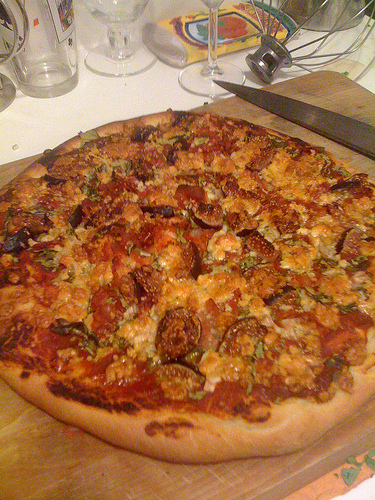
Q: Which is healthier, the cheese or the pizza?
A: The cheese is healthier than the pizza.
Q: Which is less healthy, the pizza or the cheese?
A: The pizza is less healthy than the cheese.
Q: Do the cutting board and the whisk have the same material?
A: No, the cutting board is made of wood and the whisk is made of metal.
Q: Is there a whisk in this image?
A: Yes, there is a whisk.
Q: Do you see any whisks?
A: Yes, there is a whisk.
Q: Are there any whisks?
A: Yes, there is a whisk.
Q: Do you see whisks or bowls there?
A: Yes, there is a whisk.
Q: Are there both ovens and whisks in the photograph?
A: No, there is a whisk but no ovens.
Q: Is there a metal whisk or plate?
A: Yes, there is a metal whisk.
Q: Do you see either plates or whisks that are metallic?
A: Yes, the whisk is metallic.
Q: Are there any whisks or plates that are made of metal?
A: Yes, the whisk is made of metal.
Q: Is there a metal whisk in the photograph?
A: Yes, there is a metal whisk.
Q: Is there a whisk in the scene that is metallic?
A: Yes, there is a whisk that is metallic.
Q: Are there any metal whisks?
A: Yes, there is a whisk that is made of metal.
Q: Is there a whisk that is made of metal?
A: Yes, there is a whisk that is made of metal.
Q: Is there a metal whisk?
A: Yes, there is a whisk that is made of metal.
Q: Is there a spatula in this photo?
A: No, there are no spatulas.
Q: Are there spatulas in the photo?
A: No, there are no spatulas.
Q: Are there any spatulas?
A: No, there are no spatulas.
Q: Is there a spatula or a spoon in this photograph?
A: No, there are no spatulas or spoons.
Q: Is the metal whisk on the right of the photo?
A: Yes, the whisk is on the right of the image.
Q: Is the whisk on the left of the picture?
A: No, the whisk is on the right of the image.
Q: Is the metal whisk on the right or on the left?
A: The whisk is on the right of the image.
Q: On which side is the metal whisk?
A: The whisk is on the right of the image.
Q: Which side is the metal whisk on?
A: The whisk is on the right of the image.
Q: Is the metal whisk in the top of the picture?
A: Yes, the whisk is in the top of the image.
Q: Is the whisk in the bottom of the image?
A: No, the whisk is in the top of the image.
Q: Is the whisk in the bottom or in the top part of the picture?
A: The whisk is in the top of the image.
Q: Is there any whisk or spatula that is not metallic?
A: No, there is a whisk but it is metallic.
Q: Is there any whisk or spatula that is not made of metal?
A: No, there is a whisk but it is made of metal.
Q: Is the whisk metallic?
A: Yes, the whisk is metallic.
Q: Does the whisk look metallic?
A: Yes, the whisk is metallic.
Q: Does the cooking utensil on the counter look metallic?
A: Yes, the whisk is metallic.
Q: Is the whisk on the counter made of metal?
A: Yes, the whisk is made of metal.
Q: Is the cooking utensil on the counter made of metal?
A: Yes, the whisk is made of metal.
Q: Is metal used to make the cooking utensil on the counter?
A: Yes, the whisk is made of metal.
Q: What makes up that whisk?
A: The whisk is made of metal.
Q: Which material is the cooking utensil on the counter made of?
A: The whisk is made of metal.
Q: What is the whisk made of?
A: The whisk is made of metal.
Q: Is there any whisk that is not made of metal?
A: No, there is a whisk but it is made of metal.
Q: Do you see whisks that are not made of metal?
A: No, there is a whisk but it is made of metal.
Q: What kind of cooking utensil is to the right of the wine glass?
A: The cooking utensil is a whisk.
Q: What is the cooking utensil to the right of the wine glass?
A: The cooking utensil is a whisk.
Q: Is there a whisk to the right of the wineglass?
A: Yes, there is a whisk to the right of the wineglass.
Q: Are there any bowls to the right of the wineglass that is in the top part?
A: No, there is a whisk to the right of the wine glass.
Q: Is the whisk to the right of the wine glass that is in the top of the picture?
A: Yes, the whisk is to the right of the wineglass.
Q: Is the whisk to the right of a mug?
A: No, the whisk is to the right of the wineglass.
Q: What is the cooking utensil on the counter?
A: The cooking utensil is a whisk.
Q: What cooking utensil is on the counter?
A: The cooking utensil is a whisk.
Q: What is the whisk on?
A: The whisk is on the counter.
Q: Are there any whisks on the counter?
A: Yes, there is a whisk on the counter.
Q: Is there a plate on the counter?
A: No, there is a whisk on the counter.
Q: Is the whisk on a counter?
A: Yes, the whisk is on a counter.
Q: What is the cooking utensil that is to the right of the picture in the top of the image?
A: The cooking utensil is a whisk.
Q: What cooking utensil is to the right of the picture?
A: The cooking utensil is a whisk.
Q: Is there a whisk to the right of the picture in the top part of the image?
A: Yes, there is a whisk to the right of the picture.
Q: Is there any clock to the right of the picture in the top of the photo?
A: No, there is a whisk to the right of the picture.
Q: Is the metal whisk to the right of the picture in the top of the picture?
A: Yes, the whisk is to the right of the picture.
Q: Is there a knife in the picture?
A: Yes, there is a knife.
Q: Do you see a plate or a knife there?
A: Yes, there is a knife.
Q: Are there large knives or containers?
A: Yes, there is a large knife.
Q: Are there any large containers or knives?
A: Yes, there is a large knife.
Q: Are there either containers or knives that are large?
A: Yes, the knife is large.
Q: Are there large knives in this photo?
A: Yes, there is a large knife.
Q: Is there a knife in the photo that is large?
A: Yes, there is a knife that is large.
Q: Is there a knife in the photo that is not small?
A: Yes, there is a large knife.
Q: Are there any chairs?
A: No, there are no chairs.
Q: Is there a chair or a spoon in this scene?
A: No, there are no chairs or spoons.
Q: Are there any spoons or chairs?
A: No, there are no chairs or spoons.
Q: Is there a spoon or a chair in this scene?
A: No, there are no chairs or spoons.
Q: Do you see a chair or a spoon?
A: No, there are no chairs or spoons.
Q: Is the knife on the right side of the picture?
A: Yes, the knife is on the right of the image.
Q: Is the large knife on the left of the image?
A: No, the knife is on the right of the image.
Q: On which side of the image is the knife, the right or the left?
A: The knife is on the right of the image.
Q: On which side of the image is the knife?
A: The knife is on the right of the image.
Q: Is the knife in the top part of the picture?
A: Yes, the knife is in the top of the image.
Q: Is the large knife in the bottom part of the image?
A: No, the knife is in the top of the image.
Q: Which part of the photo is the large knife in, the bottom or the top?
A: The knife is in the top of the image.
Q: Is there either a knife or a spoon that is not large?
A: No, there is a knife but it is large.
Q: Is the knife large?
A: Yes, the knife is large.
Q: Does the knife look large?
A: Yes, the knife is large.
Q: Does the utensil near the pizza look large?
A: Yes, the knife is large.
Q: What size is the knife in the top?
A: The knife is large.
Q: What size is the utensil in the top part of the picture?
A: The knife is large.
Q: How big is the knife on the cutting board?
A: The knife is large.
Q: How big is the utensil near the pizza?
A: The knife is large.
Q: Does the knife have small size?
A: No, the knife is large.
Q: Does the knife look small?
A: No, the knife is large.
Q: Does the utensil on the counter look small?
A: No, the knife is large.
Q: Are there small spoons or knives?
A: No, there is a knife but it is large.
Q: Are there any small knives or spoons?
A: No, there is a knife but it is large.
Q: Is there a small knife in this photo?
A: No, there is a knife but it is large.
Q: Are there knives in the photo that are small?
A: No, there is a knife but it is large.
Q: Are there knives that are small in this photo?
A: No, there is a knife but it is large.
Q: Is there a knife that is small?
A: No, there is a knife but it is large.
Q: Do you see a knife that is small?
A: No, there is a knife but it is large.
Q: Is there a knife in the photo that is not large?
A: No, there is a knife but it is large.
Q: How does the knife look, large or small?
A: The knife is large.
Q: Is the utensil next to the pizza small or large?
A: The knife is large.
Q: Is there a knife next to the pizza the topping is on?
A: Yes, there is a knife next to the pizza.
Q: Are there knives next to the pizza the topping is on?
A: Yes, there is a knife next to the pizza.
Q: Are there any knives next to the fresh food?
A: Yes, there is a knife next to the pizza.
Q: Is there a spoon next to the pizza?
A: No, there is a knife next to the pizza.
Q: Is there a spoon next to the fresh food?
A: No, there is a knife next to the pizza.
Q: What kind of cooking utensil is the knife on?
A: The knife is on the cutting board.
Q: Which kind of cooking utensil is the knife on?
A: The knife is on the cutting board.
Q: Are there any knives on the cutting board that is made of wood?
A: Yes, there is a knife on the cutting board.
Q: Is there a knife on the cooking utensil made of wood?
A: Yes, there is a knife on the cutting board.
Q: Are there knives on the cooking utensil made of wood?
A: Yes, there is a knife on the cutting board.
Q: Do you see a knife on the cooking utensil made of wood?
A: Yes, there is a knife on the cutting board.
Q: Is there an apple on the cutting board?
A: No, there is a knife on the cutting board.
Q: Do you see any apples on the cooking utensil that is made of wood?
A: No, there is a knife on the cutting board.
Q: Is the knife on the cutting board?
A: Yes, the knife is on the cutting board.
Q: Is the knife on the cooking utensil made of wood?
A: Yes, the knife is on the cutting board.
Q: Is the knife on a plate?
A: No, the knife is on the cutting board.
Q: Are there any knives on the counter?
A: Yes, there is a knife on the counter.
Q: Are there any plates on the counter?
A: No, there is a knife on the counter.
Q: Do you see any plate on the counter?
A: No, there is a knife on the counter.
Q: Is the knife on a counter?
A: Yes, the knife is on a counter.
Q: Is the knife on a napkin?
A: No, the knife is on a counter.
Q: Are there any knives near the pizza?
A: Yes, there is a knife near the pizza.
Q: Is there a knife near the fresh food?
A: Yes, there is a knife near the pizza.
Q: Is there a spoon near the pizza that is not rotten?
A: No, there is a knife near the pizza.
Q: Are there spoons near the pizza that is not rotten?
A: No, there is a knife near the pizza.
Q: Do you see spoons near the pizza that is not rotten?
A: No, there is a knife near the pizza.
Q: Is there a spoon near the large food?
A: No, there is a knife near the pizza.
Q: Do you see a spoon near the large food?
A: No, there is a knife near the pizza.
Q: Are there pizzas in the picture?
A: Yes, there is a pizza.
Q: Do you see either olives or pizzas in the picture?
A: Yes, there is a pizza.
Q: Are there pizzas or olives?
A: Yes, there is a pizza.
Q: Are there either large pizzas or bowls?
A: Yes, there is a large pizza.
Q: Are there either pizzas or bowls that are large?
A: Yes, the pizza is large.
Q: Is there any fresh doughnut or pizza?
A: Yes, there is a fresh pizza.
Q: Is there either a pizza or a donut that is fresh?
A: Yes, the pizza is fresh.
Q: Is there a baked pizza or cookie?
A: Yes, there is a baked pizza.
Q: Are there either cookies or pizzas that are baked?
A: Yes, the pizza is baked.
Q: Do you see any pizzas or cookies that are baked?
A: Yes, the pizza is baked.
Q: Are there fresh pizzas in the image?
A: Yes, there is a fresh pizza.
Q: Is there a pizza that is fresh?
A: Yes, there is a pizza that is fresh.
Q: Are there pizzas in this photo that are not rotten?
A: Yes, there is a fresh pizza.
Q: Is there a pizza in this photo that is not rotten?
A: Yes, there is a fresh pizza.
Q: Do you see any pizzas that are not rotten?
A: Yes, there is a fresh pizza.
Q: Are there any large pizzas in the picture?
A: Yes, there is a large pizza.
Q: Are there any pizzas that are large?
A: Yes, there is a pizza that is large.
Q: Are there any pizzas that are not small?
A: Yes, there is a large pizza.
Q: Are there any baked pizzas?
A: Yes, there is a baked pizza.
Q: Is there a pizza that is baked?
A: Yes, there is a pizza that is baked.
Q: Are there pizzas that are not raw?
A: Yes, there is a baked pizza.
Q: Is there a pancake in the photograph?
A: No, there are no pancakes.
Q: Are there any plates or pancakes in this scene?
A: No, there are no pancakes or plates.